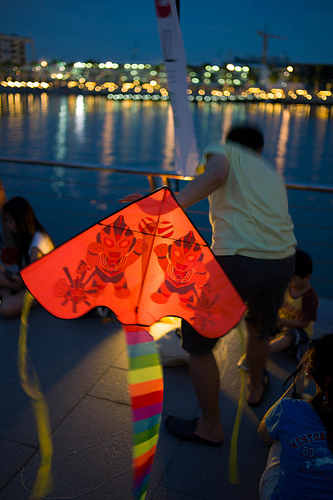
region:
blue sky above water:
[72, 13, 117, 41]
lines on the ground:
[63, 372, 110, 420]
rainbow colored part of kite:
[132, 353, 171, 438]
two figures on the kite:
[94, 215, 204, 295]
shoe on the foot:
[157, 407, 228, 467]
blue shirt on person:
[275, 407, 323, 485]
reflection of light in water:
[74, 114, 132, 139]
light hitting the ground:
[75, 337, 120, 384]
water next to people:
[76, 115, 122, 144]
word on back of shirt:
[283, 423, 324, 452]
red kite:
[20, 184, 247, 336]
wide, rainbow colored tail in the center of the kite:
[122, 322, 163, 498]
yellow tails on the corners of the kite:
[21, 289, 247, 498]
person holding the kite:
[117, 122, 297, 447]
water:
[0, 91, 331, 281]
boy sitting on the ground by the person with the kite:
[235, 244, 319, 369]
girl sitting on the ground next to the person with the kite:
[254, 333, 332, 498]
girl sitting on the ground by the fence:
[0, 194, 55, 314]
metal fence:
[1, 155, 332, 287]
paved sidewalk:
[1, 296, 331, 499]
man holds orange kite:
[49, 89, 284, 347]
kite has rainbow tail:
[95, 273, 191, 462]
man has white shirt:
[193, 142, 312, 239]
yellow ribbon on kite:
[12, 291, 52, 494]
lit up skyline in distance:
[16, 21, 315, 102]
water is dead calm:
[58, 108, 212, 179]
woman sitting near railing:
[9, 195, 57, 312]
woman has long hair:
[21, 190, 51, 251]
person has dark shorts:
[216, 253, 284, 346]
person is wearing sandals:
[166, 415, 224, 449]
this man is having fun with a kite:
[38, 150, 294, 393]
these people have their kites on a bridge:
[41, 161, 322, 367]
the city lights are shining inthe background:
[5, 45, 332, 248]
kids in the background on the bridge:
[231, 235, 332, 440]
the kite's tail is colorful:
[82, 320, 196, 496]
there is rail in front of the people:
[3, 144, 328, 301]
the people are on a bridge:
[8, 138, 332, 336]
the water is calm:
[12, 103, 325, 271]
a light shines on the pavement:
[63, 295, 254, 498]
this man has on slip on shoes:
[162, 358, 275, 476]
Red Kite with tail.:
[21, 188, 226, 466]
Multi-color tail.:
[120, 323, 165, 499]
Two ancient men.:
[88, 216, 212, 313]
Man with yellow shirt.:
[200, 120, 296, 267]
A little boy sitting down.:
[265, 246, 319, 352]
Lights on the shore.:
[3, 56, 330, 99]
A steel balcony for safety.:
[0, 153, 330, 259]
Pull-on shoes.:
[162, 371, 266, 444]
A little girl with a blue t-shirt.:
[260, 345, 327, 492]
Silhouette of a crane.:
[253, 20, 288, 66]